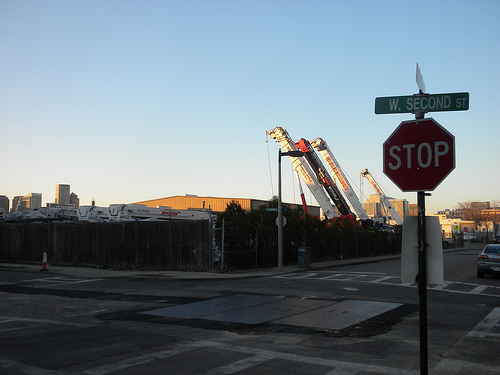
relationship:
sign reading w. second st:
[373, 91, 471, 114] [390, 95, 469, 110]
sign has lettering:
[381, 115, 459, 193] [388, 141, 451, 172]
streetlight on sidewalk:
[275, 147, 305, 271] [2, 254, 412, 283]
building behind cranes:
[134, 195, 322, 228] [267, 127, 341, 223]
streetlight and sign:
[275, 147, 305, 271] [373, 91, 471, 114]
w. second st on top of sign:
[390, 95, 469, 110] [381, 115, 459, 193]